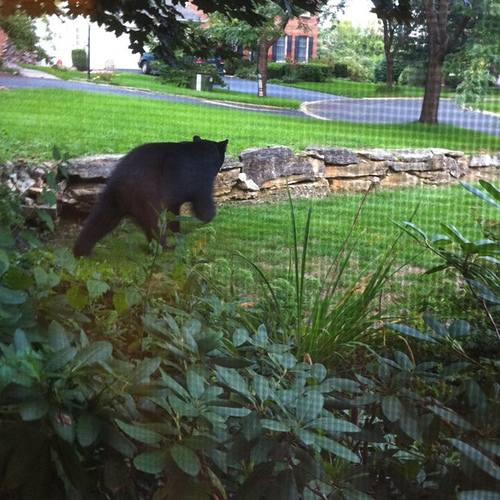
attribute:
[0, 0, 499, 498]
photo — outdoor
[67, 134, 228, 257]
bear — photo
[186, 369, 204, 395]
leaf — green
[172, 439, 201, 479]
leaf — green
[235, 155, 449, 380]
plant — leaves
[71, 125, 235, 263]
bear — backview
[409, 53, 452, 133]
tree — trunk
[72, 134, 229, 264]
black bear — roaming, free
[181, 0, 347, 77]
house — background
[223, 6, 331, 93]
house — brick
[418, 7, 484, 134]
trunk — large, tree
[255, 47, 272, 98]
trunk — tree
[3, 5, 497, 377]
window — screen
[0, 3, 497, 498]
daytime — photo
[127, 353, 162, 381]
leaf — green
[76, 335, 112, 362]
leaf — green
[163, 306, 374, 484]
leaves — tree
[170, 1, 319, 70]
house — red, brick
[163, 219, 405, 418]
plants — green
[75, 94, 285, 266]
bear — fur, black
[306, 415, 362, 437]
leaf — green